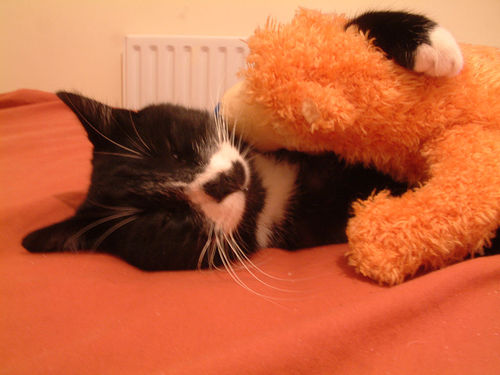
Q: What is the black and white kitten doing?
A: Sleeping.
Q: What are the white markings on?
A: A black cat.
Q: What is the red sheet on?
A: A bed.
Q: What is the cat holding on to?
A: An orange stuffed animal.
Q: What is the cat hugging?
A: Stuffed animal.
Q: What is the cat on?
A: Bed.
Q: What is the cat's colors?
A: Black and white.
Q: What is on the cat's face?
A: Whiskers.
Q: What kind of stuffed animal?
A: Teddy bear.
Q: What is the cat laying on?
A: Blanket.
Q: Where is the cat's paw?
A: Around the bear.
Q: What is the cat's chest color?
A: White.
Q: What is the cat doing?
A: Lying on a bed.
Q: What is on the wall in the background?
A: A radiator.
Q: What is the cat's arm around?
A: A stuffed animal.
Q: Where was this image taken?
A: In a bedroom.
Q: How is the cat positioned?
A: On its side, with its arm around a stuffed animal.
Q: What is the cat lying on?
A: A bed.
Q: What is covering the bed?
A: A blanket.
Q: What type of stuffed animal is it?
A: A bear.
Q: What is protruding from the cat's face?
A: Whiskers.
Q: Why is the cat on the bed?
A: It is sleeping.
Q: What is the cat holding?
A: Stuffed animal.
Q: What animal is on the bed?
A: A cat.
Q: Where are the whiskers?
A: Cat's nose.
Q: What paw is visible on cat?
A: Left paw.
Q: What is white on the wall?
A: Radiator.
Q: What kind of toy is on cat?
A: Bear.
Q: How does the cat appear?
A: Sleepy.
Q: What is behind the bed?
A: Tan wall.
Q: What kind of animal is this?
A: Cat.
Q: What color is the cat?
A: Black and white.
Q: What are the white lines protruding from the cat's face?
A: Whiskers.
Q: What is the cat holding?
A: Stuffed animal.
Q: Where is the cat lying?
A: Bed.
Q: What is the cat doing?
A: Sleeping.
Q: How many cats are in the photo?
A: One.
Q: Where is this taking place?
A: On a bed.